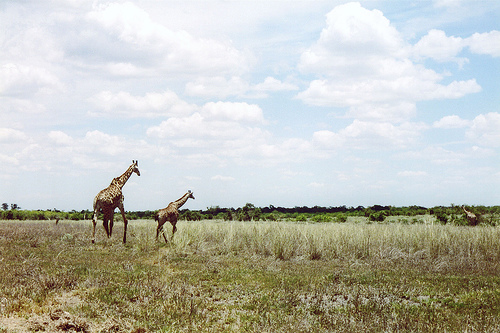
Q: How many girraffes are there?
A: Two.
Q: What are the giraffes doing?
A: Running through the field.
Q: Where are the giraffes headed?
A: Trees.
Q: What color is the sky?
A: Blue.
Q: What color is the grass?
A: Green.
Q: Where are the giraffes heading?
A: Away from the camera.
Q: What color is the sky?
A: Blue.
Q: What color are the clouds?
A: White.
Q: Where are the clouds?
A: In the sky.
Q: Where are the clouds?
A: In the sky.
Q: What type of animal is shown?
A: Giraffes.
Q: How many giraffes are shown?
A: 2.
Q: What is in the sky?
A: Clouds.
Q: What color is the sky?
A: Blue.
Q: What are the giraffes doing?
A: Walking.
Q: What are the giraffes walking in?
A: Grass.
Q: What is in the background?
A: Trees.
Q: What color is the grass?
A: Brown.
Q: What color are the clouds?
A: White.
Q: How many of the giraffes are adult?
A: 1.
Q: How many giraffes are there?
A: 2.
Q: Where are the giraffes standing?
A: In an open field.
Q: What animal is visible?
A: Giraffe.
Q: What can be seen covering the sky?
A: White clouds.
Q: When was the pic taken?
A: During the day.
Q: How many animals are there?
A: 2.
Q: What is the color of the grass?
A: Yellow.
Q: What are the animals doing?
A: Walking.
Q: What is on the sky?
A: Clouds.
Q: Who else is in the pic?
A: No one.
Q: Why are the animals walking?
A: Looking for food.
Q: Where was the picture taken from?
A: In a field.